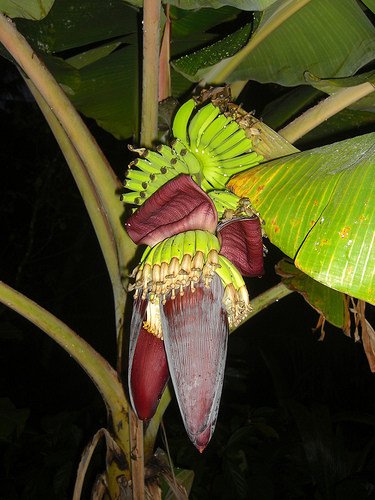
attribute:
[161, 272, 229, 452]
bulb — large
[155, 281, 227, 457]
bulb — purple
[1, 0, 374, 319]
leaves — green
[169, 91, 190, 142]
banana — green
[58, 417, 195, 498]
leaves — green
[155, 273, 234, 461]
flowery — red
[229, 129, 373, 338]
leaf — large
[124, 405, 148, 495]
stalk — green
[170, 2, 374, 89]
leaf — green, large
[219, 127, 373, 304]
leaf — large, green 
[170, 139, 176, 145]
black tip — on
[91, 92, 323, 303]
banana — red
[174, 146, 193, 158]
tip — black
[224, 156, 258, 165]
banana — green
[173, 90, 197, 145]
banana — green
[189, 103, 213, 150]
banana — green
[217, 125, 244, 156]
banana — green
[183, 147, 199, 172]
banana — green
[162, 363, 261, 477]
plant pod — large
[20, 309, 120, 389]
leaf — large, brown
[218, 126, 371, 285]
leaf — green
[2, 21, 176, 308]
branches — green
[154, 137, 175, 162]
banana — green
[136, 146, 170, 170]
banana — green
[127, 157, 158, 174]
banana — green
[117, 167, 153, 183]
banana — green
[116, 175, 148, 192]
banana — green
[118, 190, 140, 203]
banana — green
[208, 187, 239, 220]
banana — green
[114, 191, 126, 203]
tip — black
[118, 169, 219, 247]
plant pod — large